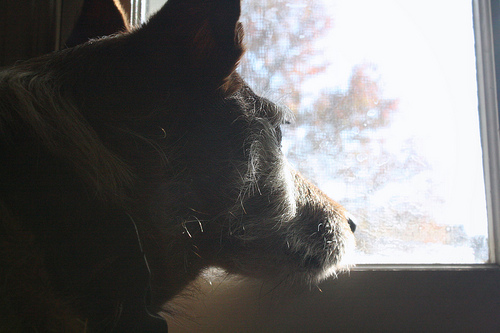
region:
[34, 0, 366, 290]
brown and white dog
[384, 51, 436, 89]
white clouds in blue sky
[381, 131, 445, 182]
white clouds in blue sky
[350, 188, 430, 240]
white clouds in blue sky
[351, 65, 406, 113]
white clouds in blue sky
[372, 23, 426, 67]
white clouds in blue sky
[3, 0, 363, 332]
a mixed colored dog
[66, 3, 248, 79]
the ears standing up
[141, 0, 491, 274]
the window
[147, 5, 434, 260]
the tall trees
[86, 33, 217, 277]
the collar on neck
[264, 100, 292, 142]
the eye of dog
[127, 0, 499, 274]
trimming of window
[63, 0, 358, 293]
the head of animal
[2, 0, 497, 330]
A dog looking out a window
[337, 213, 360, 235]
Black nose on a dog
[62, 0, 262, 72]
Ears on a dog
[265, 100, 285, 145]
Eye on a dog's head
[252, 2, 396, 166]
Tree outside a window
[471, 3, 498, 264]
White window frame on side of window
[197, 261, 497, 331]
Frame on the bottom of a window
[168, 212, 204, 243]
Buckle on a dog's collar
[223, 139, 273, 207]
White hair strands on a dog's face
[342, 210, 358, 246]
nose on the animal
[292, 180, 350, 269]
the nose is furry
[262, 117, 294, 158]
the eye is black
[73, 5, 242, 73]
the ears are pointed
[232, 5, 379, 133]
the leavesare orange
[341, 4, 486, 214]
the sky is bright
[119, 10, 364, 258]
the animal is staring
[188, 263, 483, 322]
the window sill is white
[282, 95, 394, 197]
leaves on the branches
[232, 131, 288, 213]
the white patch of fur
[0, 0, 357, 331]
scruffy hair dog at window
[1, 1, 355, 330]
dog has white and brown hair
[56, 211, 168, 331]
black plastic clip on dog collar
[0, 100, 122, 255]
band on dog collar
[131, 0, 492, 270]
glass is rectangular shaped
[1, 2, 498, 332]
dog is staring out window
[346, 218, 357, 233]
black nose on dog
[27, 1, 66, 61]
wood trim on wall above dog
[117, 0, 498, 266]
wood holding window sides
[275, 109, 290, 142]
the side of a dog's right eye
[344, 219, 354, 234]
the little black nose of a dog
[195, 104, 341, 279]
white fuzzy hair on the side of a dog's face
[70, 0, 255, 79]
perky brown ears on a dog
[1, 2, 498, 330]
Dog looking at the window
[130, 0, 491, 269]
Glass rectangular window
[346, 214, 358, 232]
Black nose of the dog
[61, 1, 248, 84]
Two pointy ears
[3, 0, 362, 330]
Side view of the dog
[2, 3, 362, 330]
Dog has white fur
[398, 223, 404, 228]
A leaf on a stem.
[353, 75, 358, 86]
A leaf on a stem.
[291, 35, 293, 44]
A leaf on a stem.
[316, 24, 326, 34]
A leaf on a stem.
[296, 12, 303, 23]
A leaf on a stem.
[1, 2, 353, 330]
dog looking through window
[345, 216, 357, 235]
black nose of dog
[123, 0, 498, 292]
white window on the wall